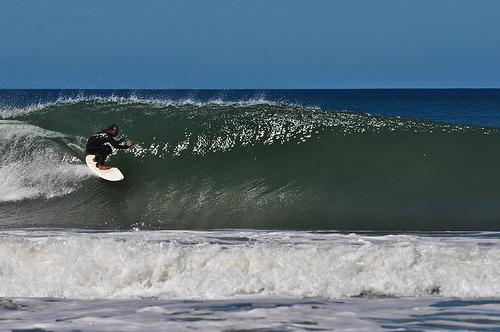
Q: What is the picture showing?
A: It is showing an ocean.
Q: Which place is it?
A: It is an ocean.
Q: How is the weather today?
A: It is cloudless.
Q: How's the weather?
A: It is cloudless.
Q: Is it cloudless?
A: Yes, it is cloudless.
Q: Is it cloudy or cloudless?
A: It is cloudless.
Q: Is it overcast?
A: No, it is cloudless.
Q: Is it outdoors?
A: Yes, it is outdoors.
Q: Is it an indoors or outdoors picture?
A: It is outdoors.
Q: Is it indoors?
A: No, it is outdoors.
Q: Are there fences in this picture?
A: No, there are no fences.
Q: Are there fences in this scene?
A: No, there are no fences.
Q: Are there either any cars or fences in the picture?
A: No, there are no fences or cars.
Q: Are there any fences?
A: No, there are no fences.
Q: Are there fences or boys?
A: No, there are no fences or boys.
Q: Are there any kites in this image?
A: No, there are no kites.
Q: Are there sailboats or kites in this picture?
A: No, there are no kites or sailboats.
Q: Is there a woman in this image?
A: No, there are no women.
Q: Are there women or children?
A: No, there are no women or children.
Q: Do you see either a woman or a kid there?
A: No, there are no women or children.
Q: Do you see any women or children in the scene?
A: No, there are no women or children.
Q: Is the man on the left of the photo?
A: Yes, the man is on the left of the image.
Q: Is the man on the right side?
A: No, the man is on the left of the image.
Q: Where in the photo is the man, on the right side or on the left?
A: The man is on the left of the image.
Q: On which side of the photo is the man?
A: The man is on the left of the image.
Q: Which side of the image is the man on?
A: The man is on the left of the image.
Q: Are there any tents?
A: No, there are no tents.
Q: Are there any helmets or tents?
A: No, there are no tents or helmets.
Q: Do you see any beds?
A: No, there are no beds.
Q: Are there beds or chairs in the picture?
A: No, there are no beds or chairs.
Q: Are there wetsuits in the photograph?
A: Yes, there is a wetsuit.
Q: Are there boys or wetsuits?
A: Yes, there is a wetsuit.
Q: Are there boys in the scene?
A: No, there are no boys.